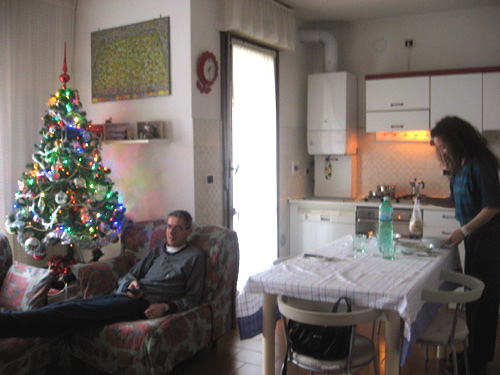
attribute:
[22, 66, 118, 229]
tree — christmas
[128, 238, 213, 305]
man — sitting, feet, holding, wearing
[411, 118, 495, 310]
woman — standing, holding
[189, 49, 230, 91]
clock — red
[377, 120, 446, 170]
light — christmas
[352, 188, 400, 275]
water — green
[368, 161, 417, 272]
bottle — tall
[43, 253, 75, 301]
bag — black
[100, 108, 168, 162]
shelf — floating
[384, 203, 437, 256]
cup — glass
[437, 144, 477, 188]
hair — curly